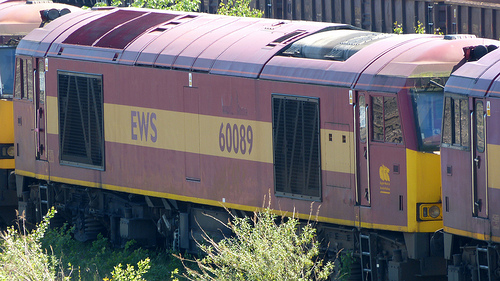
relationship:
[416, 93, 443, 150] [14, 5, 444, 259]
windscreen on train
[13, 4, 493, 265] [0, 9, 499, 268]
car on train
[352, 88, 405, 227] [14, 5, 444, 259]
door of train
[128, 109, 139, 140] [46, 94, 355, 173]
letter on stripe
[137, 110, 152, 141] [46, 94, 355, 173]
letter on stripe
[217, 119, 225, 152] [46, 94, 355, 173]
number on stripe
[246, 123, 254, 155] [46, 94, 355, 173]
number on stripe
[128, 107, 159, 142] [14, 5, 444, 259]
ews on train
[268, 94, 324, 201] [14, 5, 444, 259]
door on train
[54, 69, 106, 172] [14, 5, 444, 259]
door on train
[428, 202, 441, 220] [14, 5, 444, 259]
headlight front of train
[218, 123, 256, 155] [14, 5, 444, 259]
60089 on train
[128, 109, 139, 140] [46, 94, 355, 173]
letter on area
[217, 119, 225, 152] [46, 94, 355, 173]
number on area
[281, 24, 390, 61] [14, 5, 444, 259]
opening top of train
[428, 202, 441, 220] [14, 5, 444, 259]
light on train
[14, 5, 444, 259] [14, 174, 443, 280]
train has bottom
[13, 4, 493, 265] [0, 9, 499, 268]
engine of train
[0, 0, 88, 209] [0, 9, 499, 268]
engine of train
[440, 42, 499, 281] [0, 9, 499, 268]
engine of train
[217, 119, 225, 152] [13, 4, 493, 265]
number on engine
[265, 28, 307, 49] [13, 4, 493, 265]
vent on engine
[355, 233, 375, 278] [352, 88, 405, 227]
steps to entrance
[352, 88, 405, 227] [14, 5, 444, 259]
entrance to train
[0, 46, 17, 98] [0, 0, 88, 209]
windshield on engine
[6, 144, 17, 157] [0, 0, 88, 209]
headlight on engine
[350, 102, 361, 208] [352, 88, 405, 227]
handrail on entrance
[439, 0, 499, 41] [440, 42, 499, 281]
car behind engine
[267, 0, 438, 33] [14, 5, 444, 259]
car behind engine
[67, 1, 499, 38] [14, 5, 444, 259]
train behind segment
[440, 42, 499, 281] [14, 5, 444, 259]
segment front of one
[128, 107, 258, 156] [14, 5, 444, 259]
writing on train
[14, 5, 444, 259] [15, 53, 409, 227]
train has side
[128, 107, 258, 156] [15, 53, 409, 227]
writing on side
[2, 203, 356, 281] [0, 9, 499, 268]
bushes next to train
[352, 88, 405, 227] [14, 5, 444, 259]
door on train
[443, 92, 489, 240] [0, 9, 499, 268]
door on train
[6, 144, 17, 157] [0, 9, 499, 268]
light on train